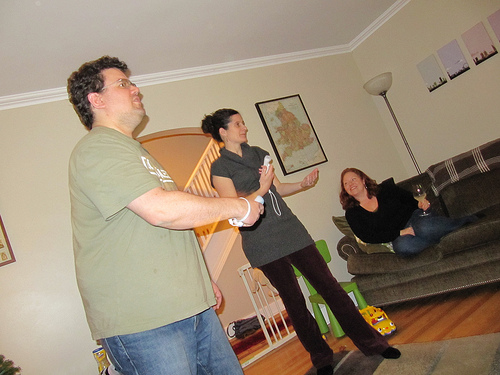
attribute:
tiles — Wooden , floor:
[368, 290, 493, 357]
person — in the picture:
[62, 50, 224, 373]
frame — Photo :
[255, 93, 335, 178]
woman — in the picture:
[330, 168, 481, 260]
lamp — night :
[361, 70, 396, 97]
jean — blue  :
[95, 304, 250, 372]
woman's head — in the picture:
[198, 107, 253, 150]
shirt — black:
[340, 185, 415, 244]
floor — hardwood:
[227, 297, 499, 372]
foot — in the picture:
[370, 343, 413, 363]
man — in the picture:
[61, 54, 262, 374]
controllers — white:
[241, 153, 278, 243]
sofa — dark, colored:
[337, 146, 495, 300]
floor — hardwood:
[242, 280, 499, 373]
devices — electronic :
[249, 148, 286, 201]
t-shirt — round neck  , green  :
[64, 111, 221, 337]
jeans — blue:
[91, 321, 256, 371]